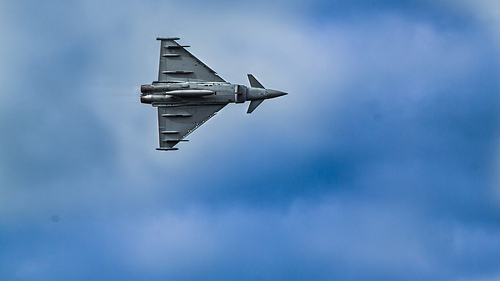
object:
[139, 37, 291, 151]
plane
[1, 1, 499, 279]
sky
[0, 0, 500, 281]
clouds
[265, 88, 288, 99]
tip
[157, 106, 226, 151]
wings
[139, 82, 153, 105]
tail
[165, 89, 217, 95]
engine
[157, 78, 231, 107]
underbelly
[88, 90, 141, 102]
fire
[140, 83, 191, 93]
fuel tank